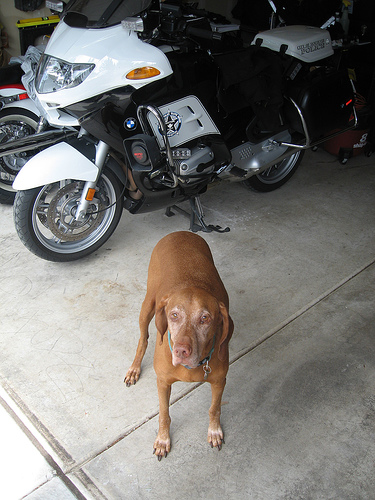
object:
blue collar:
[167, 327, 216, 371]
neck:
[157, 317, 230, 372]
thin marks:
[29, 329, 110, 408]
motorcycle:
[10, 0, 336, 266]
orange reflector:
[85, 188, 96, 201]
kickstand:
[164, 194, 212, 234]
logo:
[121, 115, 138, 132]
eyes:
[200, 313, 210, 324]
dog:
[123, 230, 236, 461]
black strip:
[0, 394, 88, 499]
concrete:
[0, 146, 375, 496]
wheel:
[12, 168, 126, 262]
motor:
[145, 90, 224, 154]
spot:
[65, 264, 140, 329]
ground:
[0, 107, 375, 498]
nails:
[152, 448, 156, 455]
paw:
[153, 435, 171, 462]